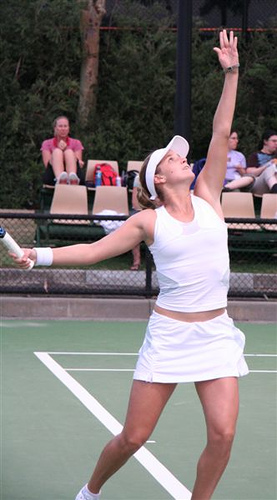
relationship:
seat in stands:
[53, 184, 90, 222] [32, 153, 275, 264]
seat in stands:
[92, 184, 132, 226] [32, 153, 275, 264]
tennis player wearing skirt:
[6, 28, 249, 498] [143, 311, 254, 386]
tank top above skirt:
[147, 193, 231, 310] [131, 309, 250, 383]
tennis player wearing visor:
[6, 28, 249, 498] [142, 134, 191, 202]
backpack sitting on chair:
[93, 161, 120, 186] [68, 169, 115, 210]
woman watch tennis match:
[37, 114, 83, 185] [3, 23, 270, 498]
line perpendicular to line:
[32, 342, 275, 358] [32, 343, 197, 498]